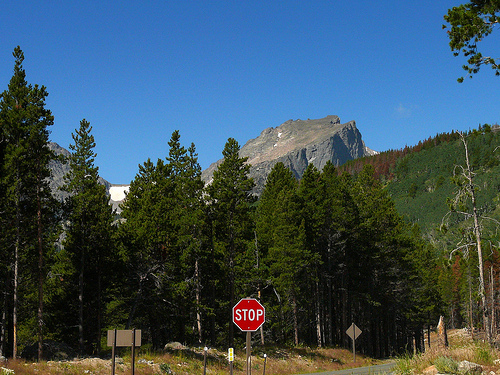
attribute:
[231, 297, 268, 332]
sign — triangular 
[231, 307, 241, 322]
letter — white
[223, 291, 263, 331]
signboard — red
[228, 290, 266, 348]
sign — red, white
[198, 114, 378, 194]
mountain — big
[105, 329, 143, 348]
sign — metal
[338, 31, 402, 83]
sky — blue 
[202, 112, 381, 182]
mountain — tall 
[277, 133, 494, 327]
hill — grassy 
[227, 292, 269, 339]
signboard — red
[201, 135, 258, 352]
tree — tall 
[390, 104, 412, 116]
cloud — white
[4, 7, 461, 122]
sky — blue 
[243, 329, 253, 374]
pole — gray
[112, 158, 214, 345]
tree — tall, evergreen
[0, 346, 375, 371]
hill — grassy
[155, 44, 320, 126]
clouds — white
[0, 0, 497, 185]
sky — blue,  blue 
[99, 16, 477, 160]
sky — blue 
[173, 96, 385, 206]
mountain — large